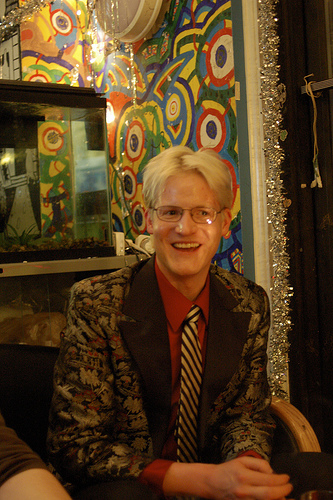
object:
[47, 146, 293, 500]
man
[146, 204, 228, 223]
glasses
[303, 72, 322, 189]
tinsel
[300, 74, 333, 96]
handle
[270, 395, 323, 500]
chair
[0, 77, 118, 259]
fish tank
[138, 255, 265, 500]
shirt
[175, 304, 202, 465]
tie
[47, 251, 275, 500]
jacket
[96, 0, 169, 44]
clock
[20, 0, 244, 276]
wall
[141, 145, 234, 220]
hair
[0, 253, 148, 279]
table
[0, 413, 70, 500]
arm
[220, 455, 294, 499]
hands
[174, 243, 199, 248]
teeth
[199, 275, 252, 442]
lapel